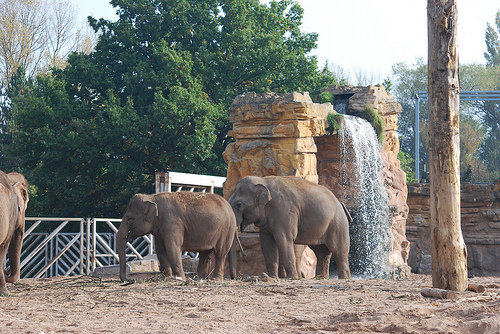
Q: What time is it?
A: Afternoon.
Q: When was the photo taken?
A: During the daytime.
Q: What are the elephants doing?
A: Standing.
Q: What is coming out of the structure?
A: Water.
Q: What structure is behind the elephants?
A: A waterfall.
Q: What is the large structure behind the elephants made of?
A: Stone.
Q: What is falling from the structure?
A: Water.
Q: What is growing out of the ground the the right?
A: A tree.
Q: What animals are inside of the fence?
A: Elephants.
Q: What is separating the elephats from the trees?
A: A fence.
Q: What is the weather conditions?
A: Sunny.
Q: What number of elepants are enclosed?
A: Three.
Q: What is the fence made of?
A: Metal.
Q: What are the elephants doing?
A: Standing.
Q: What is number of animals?
A: Three.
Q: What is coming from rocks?
A: Water.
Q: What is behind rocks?
A: Trees.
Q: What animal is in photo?
A: Elephant.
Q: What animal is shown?
A: Elephants.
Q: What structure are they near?
A: Rock waterfall.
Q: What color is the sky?
A: Blue.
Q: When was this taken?
A: Daytime.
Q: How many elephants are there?
A: 3.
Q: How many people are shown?
A: 0.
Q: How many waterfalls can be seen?
A: 1.